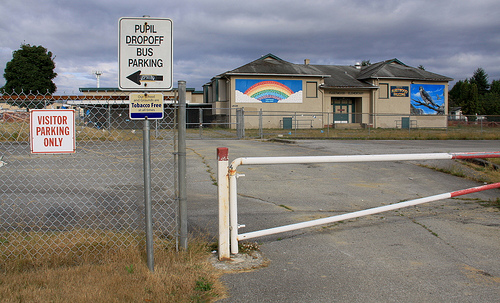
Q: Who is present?
A: Nobody.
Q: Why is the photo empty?
A: There is no one.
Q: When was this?
A: Daytime.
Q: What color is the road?
A: Grey.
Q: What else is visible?
A: Houses.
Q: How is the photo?
A: Clear.